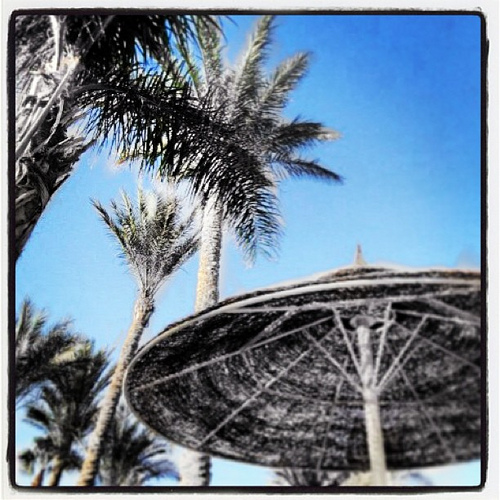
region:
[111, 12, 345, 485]
palm tree is next to palm tree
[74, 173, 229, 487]
palm tree is next to palm tree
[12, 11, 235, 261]
palm tree is next to palm tree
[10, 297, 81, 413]
palm tree is next to palm tree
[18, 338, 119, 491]
palm tree is next to palm tree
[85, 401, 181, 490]
palm tree is next to palm tree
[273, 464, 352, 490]
palm tree is next to palm tree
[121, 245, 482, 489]
beach umbrella under palm tree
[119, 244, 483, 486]
beach umbrella under blue sky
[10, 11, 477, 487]
blue sky above beach umbrella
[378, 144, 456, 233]
Bright blue part of sky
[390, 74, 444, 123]
Bright blue part of sky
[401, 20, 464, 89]
Bright blue part of sky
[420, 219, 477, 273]
Bright blue part of sky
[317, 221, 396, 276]
Bright blue part of sky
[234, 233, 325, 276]
Bright blue part of sky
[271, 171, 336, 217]
Bright blue part of sky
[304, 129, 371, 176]
Bright blue part of sky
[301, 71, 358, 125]
Bright blue part of sky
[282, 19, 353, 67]
Bright blue part of sky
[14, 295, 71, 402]
Black and white tree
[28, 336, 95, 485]
Black and white tree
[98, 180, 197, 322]
Black and white tree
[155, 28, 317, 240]
Black and white tree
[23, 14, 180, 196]
Black and white tree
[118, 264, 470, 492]
Black and white umbrella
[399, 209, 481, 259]
Part of the blue sky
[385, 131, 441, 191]
Part of the blue sky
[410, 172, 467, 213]
Part of the blue sky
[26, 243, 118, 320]
Part of the blue sky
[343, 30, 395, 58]
this is the sky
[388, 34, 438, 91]
the sky is blue in color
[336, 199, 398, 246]
the sky has clouds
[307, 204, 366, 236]
the clouds are white in color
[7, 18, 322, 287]
these are some trees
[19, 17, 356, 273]
the trees are tall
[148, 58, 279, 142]
the leaves are big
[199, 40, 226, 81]
the leaves are green in color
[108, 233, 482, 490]
this is an umbrella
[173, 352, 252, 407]
the umbrella is thatched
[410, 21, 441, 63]
Part of a blue sky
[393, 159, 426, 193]
Part of a blue sky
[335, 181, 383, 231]
Part of a blue sky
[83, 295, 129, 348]
Part of a blue sky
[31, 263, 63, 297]
Part of a blue sky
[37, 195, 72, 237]
Part of a blue sky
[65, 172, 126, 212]
Part of a blue sky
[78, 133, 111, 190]
Part of a blue sky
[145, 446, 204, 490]
Part of a blue sky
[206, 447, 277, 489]
Part of a blue sky